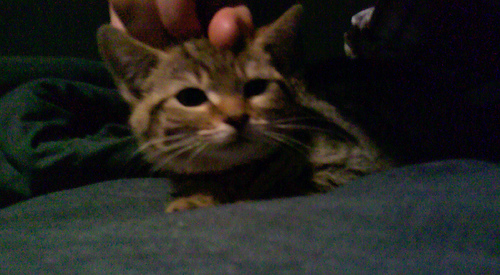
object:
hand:
[108, 0, 285, 52]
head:
[87, 8, 309, 176]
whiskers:
[128, 115, 329, 176]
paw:
[162, 190, 216, 214]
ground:
[366, 157, 404, 179]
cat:
[90, 3, 397, 215]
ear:
[95, 23, 169, 100]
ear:
[256, 3, 303, 54]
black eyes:
[171, 85, 209, 109]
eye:
[239, 78, 265, 97]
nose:
[223, 102, 247, 123]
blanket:
[0, 29, 160, 210]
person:
[102, 0, 257, 54]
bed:
[4, 130, 500, 275]